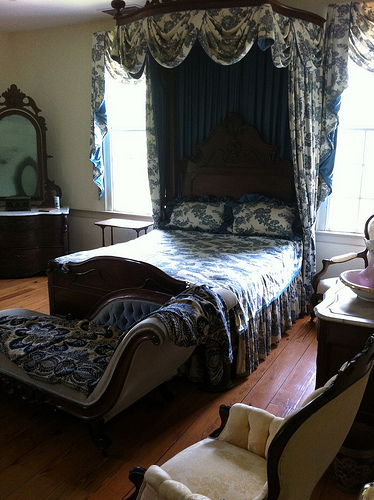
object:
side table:
[93, 217, 155, 244]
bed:
[44, 108, 310, 389]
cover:
[54, 224, 308, 378]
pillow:
[233, 194, 297, 236]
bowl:
[339, 269, 372, 306]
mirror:
[0, 111, 38, 198]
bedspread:
[56, 205, 302, 331]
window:
[106, 57, 155, 218]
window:
[320, 33, 374, 238]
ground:
[0, 254, 373, 499]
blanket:
[149, 285, 236, 387]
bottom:
[45, 253, 240, 390]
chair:
[128, 352, 373, 498]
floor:
[1, 253, 373, 498]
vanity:
[0, 83, 70, 281]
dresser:
[0, 206, 69, 278]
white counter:
[0, 207, 69, 218]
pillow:
[168, 193, 226, 231]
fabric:
[164, 237, 204, 261]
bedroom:
[0, 10, 371, 498]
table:
[313, 275, 374, 389]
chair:
[0, 285, 237, 456]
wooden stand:
[98, 419, 107, 457]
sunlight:
[329, 213, 336, 228]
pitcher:
[350, 275, 356, 279]